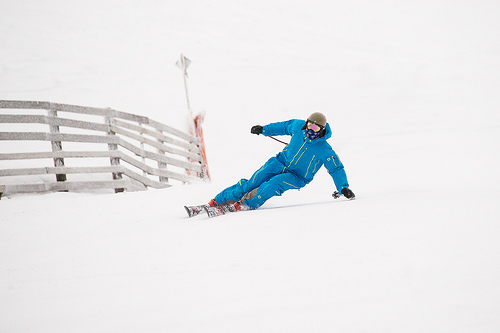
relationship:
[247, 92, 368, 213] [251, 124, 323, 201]
man wearing suit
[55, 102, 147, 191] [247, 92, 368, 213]
fence near man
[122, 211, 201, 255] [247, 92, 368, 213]
snow near man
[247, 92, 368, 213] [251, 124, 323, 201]
man wearing blue suit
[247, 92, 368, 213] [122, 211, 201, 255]
man with snow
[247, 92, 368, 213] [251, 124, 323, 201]
man has suit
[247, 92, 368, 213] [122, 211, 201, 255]
man at snow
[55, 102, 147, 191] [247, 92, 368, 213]
fence close to man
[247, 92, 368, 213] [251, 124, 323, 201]
man with suit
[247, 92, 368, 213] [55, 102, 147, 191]
man close to fence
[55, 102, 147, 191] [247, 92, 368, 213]
fence close man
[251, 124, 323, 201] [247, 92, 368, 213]
suit with man